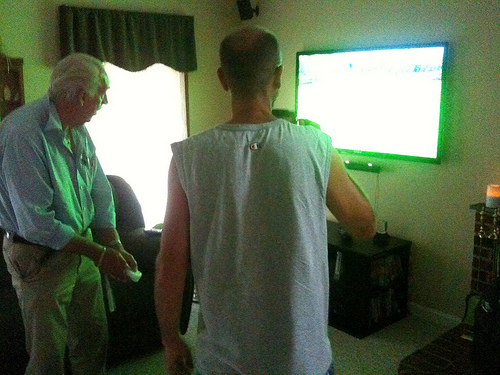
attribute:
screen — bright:
[296, 45, 443, 158]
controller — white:
[123, 258, 146, 285]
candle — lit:
[463, 168, 499, 205]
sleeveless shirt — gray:
[169, 116, 338, 371]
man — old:
[9, 48, 141, 365]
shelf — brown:
[1, 59, 31, 99]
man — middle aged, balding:
[153, 22, 380, 373]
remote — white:
[123, 261, 143, 284]